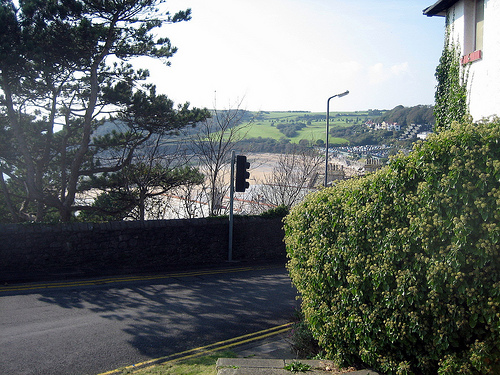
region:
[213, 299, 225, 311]
part of a shadow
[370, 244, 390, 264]
part of a bush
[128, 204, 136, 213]
part of a branch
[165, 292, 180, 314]
part of a shadow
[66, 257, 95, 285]
part of a wall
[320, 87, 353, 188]
Lamp post on the background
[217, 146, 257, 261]
A small traffic lights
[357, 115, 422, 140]
Building on the background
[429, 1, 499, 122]
Vines on the white wall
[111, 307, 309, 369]
Two yeallow lines on the road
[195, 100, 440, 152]
Green grass on the hill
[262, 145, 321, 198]
Thin branches without leaves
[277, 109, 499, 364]
A big green bush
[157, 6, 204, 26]
Tip of the pine tree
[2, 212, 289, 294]
A wall at the left side of the road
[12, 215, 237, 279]
Gate is made of wood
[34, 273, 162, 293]
Yellow paint on the road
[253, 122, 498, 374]
Green bushes on the side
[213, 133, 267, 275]
A pole with a light on it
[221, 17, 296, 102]
Blue is the color of the sky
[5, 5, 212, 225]
The trees are outside of the gate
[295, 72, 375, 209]
One pole in the shot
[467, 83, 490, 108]
A white building on the side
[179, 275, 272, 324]
shadow of the tree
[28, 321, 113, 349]
street made of asphalt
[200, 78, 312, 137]
hill in the background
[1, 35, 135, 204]
the tree is shaded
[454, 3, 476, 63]
window of the house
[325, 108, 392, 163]
top of the building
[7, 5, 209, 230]
tree with leaves on it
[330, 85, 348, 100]
lamp on a pole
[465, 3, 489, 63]
window on the side of the building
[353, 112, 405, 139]
small village in the distance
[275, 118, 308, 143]
group of bushes in the field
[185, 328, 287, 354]
yellow paint on the ground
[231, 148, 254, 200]
traffic light on a pole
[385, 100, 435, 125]
trees on the mountain side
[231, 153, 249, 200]
black traffic signal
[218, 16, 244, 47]
whtie clouds in blue sky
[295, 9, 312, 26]
whtie clouds in blue sky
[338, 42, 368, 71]
whtie clouds in blue sky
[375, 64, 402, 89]
whtie clouds in blue sky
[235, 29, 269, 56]
whtie clouds in blue sky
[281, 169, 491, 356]
Bush in the corner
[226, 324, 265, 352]
Lines on the road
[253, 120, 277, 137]
Grass in the distance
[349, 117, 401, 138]
ouses in the distance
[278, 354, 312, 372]
Grass growing from cracks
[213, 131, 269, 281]
this is a stop light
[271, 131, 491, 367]
this is a large bush